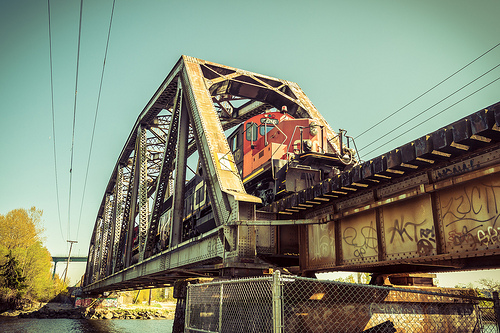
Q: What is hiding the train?
A: A bridge.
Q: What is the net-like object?
A: A chain link fence.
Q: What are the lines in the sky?
A: Power lines.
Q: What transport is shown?
A: A train.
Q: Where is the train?
A: A bridge.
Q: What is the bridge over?
A: Water.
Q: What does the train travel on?
A: Tracks.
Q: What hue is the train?
A: Red.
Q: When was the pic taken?
A: Morning.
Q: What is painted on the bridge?
A: Gaffitti.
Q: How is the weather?
A: Clear and sunny.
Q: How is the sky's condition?
A: Blue and clear.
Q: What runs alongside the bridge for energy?
A: Power lines.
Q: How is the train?
A: It is a red passenger train.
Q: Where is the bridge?
A: On a river.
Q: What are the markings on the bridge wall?
A: Graffiti.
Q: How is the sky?
A: Blue sky is apparently cloudless.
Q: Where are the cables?
A: The power cables are running overhead, sharp against the blue sky.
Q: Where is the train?
A: On a bridge over a river.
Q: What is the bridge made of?
A: Strong steel girders painted white.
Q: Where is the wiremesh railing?
A: Edging the maintenance deck under the bridge.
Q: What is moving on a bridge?
A: A train.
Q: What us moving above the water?
A: A train.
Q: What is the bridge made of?
A: Steel.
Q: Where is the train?
A: Bridge.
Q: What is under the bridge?
A: Water.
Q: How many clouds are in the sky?
A: None.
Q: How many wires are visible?
A: 6.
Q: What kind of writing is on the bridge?
A: Graffiti.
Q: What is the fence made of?
A: Metal.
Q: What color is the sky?
A: Blue.